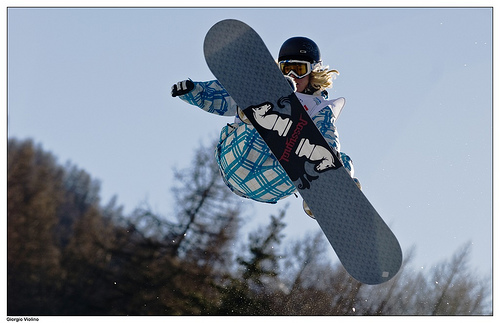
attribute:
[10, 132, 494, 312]
tree — evergreen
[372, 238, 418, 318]
tree — evergreen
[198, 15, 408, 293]
snowboard — patterned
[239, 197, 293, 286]
tree — evergreen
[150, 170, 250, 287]
evergreen tree — evergreen 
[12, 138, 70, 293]
evergreen tree — behind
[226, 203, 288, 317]
tree — evergreen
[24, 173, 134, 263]
tree — evergreen, behind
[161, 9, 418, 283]
snow boarder — behind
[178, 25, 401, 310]
snow boarder — behind